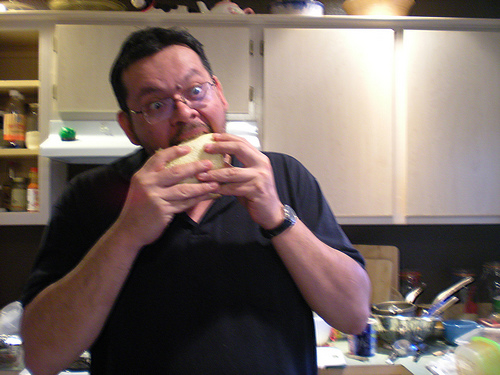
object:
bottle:
[9, 177, 27, 212]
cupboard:
[0, 29, 40, 213]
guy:
[20, 25, 370, 375]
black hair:
[109, 25, 216, 129]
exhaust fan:
[41, 121, 261, 165]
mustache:
[170, 121, 214, 146]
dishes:
[370, 275, 477, 365]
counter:
[0, 302, 500, 375]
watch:
[260, 204, 298, 240]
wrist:
[262, 205, 321, 242]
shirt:
[19, 148, 366, 375]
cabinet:
[0, 23, 39, 225]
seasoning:
[0, 89, 37, 212]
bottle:
[3, 89, 26, 148]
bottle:
[26, 167, 38, 213]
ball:
[58, 127, 76, 141]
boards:
[324, 364, 410, 374]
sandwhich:
[154, 133, 234, 226]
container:
[453, 336, 500, 374]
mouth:
[177, 131, 208, 145]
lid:
[471, 336, 499, 375]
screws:
[249, 39, 254, 55]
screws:
[249, 86, 255, 102]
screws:
[259, 40, 263, 55]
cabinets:
[49, 9, 499, 225]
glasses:
[124, 79, 217, 125]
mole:
[177, 84, 183, 90]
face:
[121, 43, 221, 156]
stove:
[69, 351, 90, 371]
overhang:
[39, 138, 259, 160]